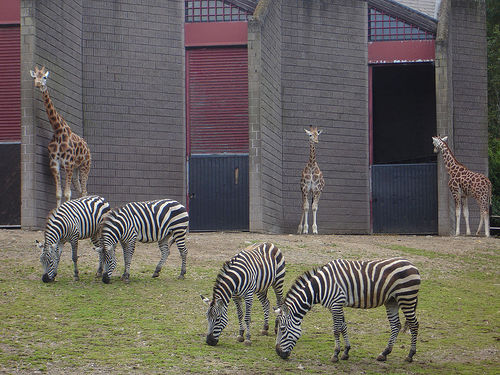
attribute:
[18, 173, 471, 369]
zebras — stripes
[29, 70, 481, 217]
giraffes — three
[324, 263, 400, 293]
stripes — black, white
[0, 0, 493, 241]
wall — gray